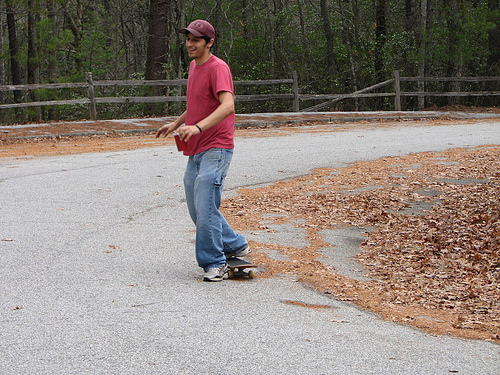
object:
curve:
[214, 141, 500, 373]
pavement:
[0, 110, 498, 373]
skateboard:
[228, 252, 255, 283]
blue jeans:
[181, 146, 249, 271]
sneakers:
[201, 241, 252, 282]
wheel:
[248, 270, 255, 279]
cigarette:
[172, 132, 180, 137]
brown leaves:
[352, 153, 500, 312]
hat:
[179, 19, 216, 40]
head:
[184, 18, 217, 58]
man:
[154, 18, 252, 282]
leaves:
[242, 143, 498, 327]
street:
[1, 110, 500, 372]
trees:
[1, 0, 498, 127]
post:
[0, 71, 300, 124]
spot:
[284, 148, 500, 375]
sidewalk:
[0, 119, 500, 357]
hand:
[176, 125, 199, 142]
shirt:
[179, 57, 235, 153]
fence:
[0, 71, 500, 126]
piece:
[303, 67, 395, 113]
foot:
[222, 240, 252, 260]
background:
[7, 0, 500, 116]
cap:
[179, 19, 219, 40]